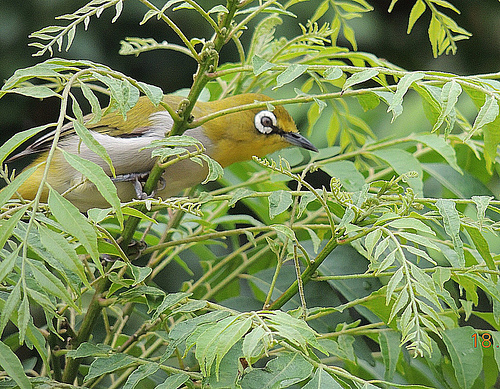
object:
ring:
[254, 110, 277, 136]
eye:
[261, 118, 273, 128]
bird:
[0, 90, 322, 214]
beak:
[286, 132, 320, 153]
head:
[206, 90, 321, 170]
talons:
[109, 171, 168, 202]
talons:
[98, 238, 149, 267]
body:
[46, 88, 223, 216]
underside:
[58, 108, 220, 214]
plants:
[3, 0, 498, 388]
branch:
[50, 0, 250, 388]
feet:
[103, 168, 170, 263]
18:
[469, 330, 493, 351]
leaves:
[343, 207, 458, 359]